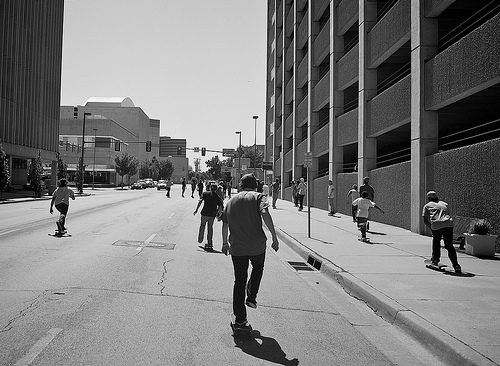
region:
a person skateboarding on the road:
[35, 165, 86, 252]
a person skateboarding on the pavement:
[400, 187, 470, 293]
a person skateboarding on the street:
[37, 167, 91, 245]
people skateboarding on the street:
[42, 175, 282, 361]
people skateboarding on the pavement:
[292, 172, 473, 279]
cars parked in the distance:
[115, 151, 158, 363]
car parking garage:
[265, 27, 493, 195]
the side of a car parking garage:
[264, 12, 488, 159]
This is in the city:
[0, 0, 492, 365]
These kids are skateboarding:
[50, 119, 475, 351]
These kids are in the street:
[20, 150, 282, 353]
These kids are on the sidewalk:
[274, 160, 472, 275]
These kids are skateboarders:
[42, 147, 490, 358]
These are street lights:
[85, 118, 267, 190]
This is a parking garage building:
[258, 5, 498, 280]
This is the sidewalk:
[255, 170, 497, 351]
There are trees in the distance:
[112, 148, 187, 190]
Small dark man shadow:
[254, 328, 306, 365]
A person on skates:
[47, 175, 79, 240]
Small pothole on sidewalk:
[288, 253, 326, 275]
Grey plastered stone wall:
[455, 155, 492, 197]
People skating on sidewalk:
[349, 178, 473, 287]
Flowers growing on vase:
[465, 218, 497, 257]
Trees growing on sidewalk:
[116, 150, 136, 181]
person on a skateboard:
[218, 171, 289, 344]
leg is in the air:
[243, 285, 260, 307]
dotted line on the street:
[6, 197, 188, 364]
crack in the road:
[154, 250, 179, 296]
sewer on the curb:
[284, 246, 327, 276]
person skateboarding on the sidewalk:
[409, 185, 477, 277]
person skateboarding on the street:
[43, 170, 89, 236]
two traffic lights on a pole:
[171, 141, 213, 159]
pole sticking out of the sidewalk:
[298, 138, 324, 247]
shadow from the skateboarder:
[224, 309, 299, 364]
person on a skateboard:
[212, 163, 289, 343]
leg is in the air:
[243, 288, 257, 311]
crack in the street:
[149, 248, 181, 296]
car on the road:
[154, 177, 167, 191]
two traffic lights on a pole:
[166, 142, 212, 161]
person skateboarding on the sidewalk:
[414, 190, 470, 280]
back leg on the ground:
[447, 254, 466, 276]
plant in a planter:
[463, 213, 499, 256]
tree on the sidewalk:
[106, 151, 133, 186]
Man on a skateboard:
[193, 155, 298, 345]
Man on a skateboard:
[403, 187, 475, 286]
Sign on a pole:
[296, 146, 333, 243]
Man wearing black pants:
[203, 170, 294, 332]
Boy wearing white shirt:
[347, 187, 387, 242]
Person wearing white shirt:
[38, 169, 80, 247]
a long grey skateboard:
[228, 308, 247, 329]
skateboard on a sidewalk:
[424, 255, 449, 274]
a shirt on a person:
[418, 200, 453, 230]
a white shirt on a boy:
[351, 198, 381, 222]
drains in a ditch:
[288, 248, 319, 274]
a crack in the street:
[153, 255, 173, 297]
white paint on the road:
[6, 324, 63, 364]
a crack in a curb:
[335, 271, 408, 318]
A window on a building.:
[353, 115, 411, 170]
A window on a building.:
[338, 133, 371, 172]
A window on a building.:
[362, 34, 422, 96]